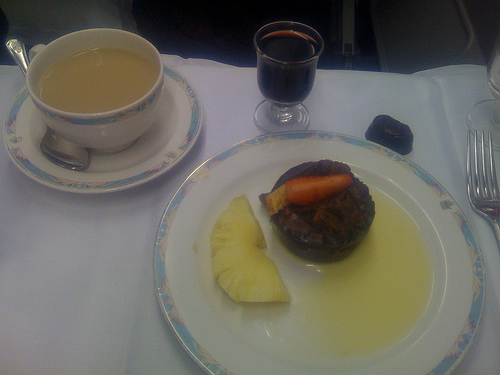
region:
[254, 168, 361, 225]
Orange carrot topping on meat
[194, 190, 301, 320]
Slice of pineapple on plate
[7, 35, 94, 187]
Silver spoon on saucer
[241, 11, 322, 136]
Full glass of dark liquid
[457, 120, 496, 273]
Silver fork on white table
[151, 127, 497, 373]
Blue and white plate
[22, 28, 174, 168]
Cup with light brown gravy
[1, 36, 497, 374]
White table with food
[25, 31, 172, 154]
White and blue cup on white and blue saucer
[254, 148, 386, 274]
Piece of dark brown meat on plate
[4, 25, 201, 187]
A bowl of soup on small plate with a spoon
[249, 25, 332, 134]
A small glass of wine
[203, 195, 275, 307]
A fresh yellow pineapple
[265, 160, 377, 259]
a piece of meat with a cooked carrot on top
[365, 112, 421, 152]
A piece of dark chocolate candy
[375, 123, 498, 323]
A silver fork on table next to dinner plate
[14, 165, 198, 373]
A white dinner table cloth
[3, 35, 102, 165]
Soup in soup bowl with spoon and plate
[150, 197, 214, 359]
design on edge of dinner plate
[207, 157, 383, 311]
meat with cooked carrot and pineapple on the side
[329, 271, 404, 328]
yellow liquid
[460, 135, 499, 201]
a silver fork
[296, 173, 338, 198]
a carrot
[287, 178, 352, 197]
the carrot is orange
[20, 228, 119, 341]
a white table cloth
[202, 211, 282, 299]
yellow pineapple on the plate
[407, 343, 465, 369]
plate is white and blue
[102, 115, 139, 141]
a bowl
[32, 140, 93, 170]
a spoon on the plate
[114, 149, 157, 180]
a plate on the table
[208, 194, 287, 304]
slice of pineapple on a white plate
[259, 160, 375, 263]
meat with a carrot on top sitting on a white plate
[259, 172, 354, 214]
orange baby carrot on top of meat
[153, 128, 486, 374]
white plate with blue trim on the table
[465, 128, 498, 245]
silver fork on the table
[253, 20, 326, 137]
glass of brown liquid on the table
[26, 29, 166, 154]
bowl of soup on the table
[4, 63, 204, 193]
white saucer with blue trim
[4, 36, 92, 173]
silver spoon on the table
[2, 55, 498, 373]
white table cloth on the table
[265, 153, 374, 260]
Carrot on top of meat.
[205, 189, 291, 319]
Piece of pineapple on plate.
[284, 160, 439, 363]
Sauce under and around food.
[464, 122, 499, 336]
Silver fork on table.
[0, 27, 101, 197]
Spoon an saucer plate.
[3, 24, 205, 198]
Cup of coffee on saucer.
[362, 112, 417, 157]
Piece of chocolate candy.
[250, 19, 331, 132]
Glass of grape juice.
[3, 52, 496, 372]
White tablecloth covering table.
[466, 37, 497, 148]
Empty wine glass.